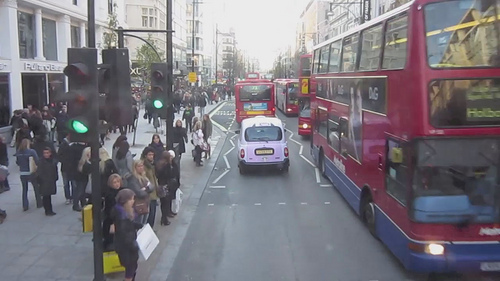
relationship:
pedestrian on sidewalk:
[34, 145, 60, 218] [0, 81, 232, 278]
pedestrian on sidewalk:
[13, 136, 46, 213] [0, 81, 232, 278]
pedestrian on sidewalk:
[110, 187, 148, 280] [0, 81, 232, 278]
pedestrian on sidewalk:
[145, 129, 167, 163] [0, 81, 232, 278]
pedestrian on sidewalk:
[114, 136, 137, 191] [0, 81, 232, 278]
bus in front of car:
[227, 74, 280, 125] [233, 112, 293, 175]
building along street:
[1, 0, 123, 142] [168, 98, 406, 279]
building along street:
[155, 0, 243, 107] [168, 98, 406, 279]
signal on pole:
[64, 44, 99, 139] [70, 4, 107, 279]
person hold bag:
[73, 120, 186, 256] [78, 173, 163, 273]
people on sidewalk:
[114, 188, 139, 276] [1, 97, 220, 279]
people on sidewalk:
[157, 150, 175, 222] [1, 97, 220, 279]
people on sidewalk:
[170, 120, 184, 168] [1, 97, 220, 279]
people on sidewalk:
[37, 147, 60, 213] [1, 97, 220, 279]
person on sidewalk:
[14, 137, 40, 210] [1, 97, 220, 279]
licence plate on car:
[250, 146, 277, 155] [236, 115, 289, 172]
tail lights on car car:
[283, 146, 288, 155] [236, 114, 290, 175]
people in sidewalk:
[0, 73, 229, 280] [0, 81, 232, 278]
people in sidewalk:
[10, 103, 103, 205] [1, 97, 220, 279]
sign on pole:
[185, 69, 197, 84] [183, 0, 200, 91]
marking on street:
[210, 98, 239, 195] [168, 98, 406, 279]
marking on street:
[285, 122, 330, 188] [168, 98, 406, 279]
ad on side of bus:
[317, 74, 390, 107] [308, 0, 496, 280]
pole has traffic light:
[87, 2, 102, 279] [64, 47, 96, 139]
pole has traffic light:
[161, 0, 172, 145] [100, 44, 136, 131]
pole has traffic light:
[161, 0, 172, 145] [148, 63, 170, 118]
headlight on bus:
[426, 241, 445, 256] [306, 2, 493, 270]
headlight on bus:
[287, 106, 292, 111] [274, 76, 301, 116]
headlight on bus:
[300, 121, 308, 128] [298, 53, 313, 135]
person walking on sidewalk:
[14, 138, 40, 209] [1, 97, 220, 279]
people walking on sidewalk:
[37, 147, 60, 216] [1, 97, 220, 279]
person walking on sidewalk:
[55, 133, 79, 203] [1, 97, 220, 279]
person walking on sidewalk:
[68, 144, 91, 210] [1, 97, 220, 279]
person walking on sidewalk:
[111, 138, 138, 174] [1, 97, 220, 279]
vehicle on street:
[235, 112, 275, 168] [168, 98, 406, 279]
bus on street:
[306, 2, 493, 270] [168, 98, 406, 279]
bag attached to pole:
[81, 206, 95, 233] [76, 1, 120, 279]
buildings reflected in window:
[441, 19, 498, 116] [421, 0, 498, 66]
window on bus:
[421, 0, 498, 66] [306, 2, 493, 270]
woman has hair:
[105, 194, 168, 280] [116, 188, 133, 201]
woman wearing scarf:
[105, 194, 168, 280] [109, 204, 133, 219]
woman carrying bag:
[105, 194, 168, 280] [134, 219, 161, 259]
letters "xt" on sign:
[125, 60, 142, 80] [120, 56, 150, 81]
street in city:
[212, 94, 326, 279] [29, 10, 465, 257]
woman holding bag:
[105, 194, 168, 280] [137, 217, 159, 259]